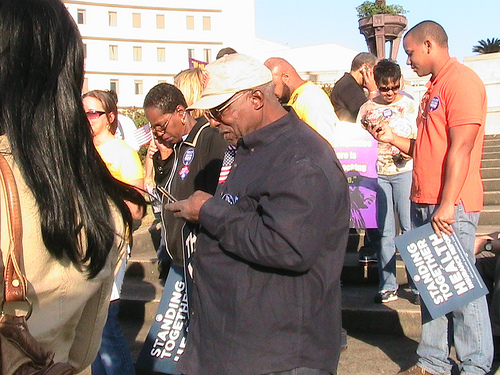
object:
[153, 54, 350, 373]
old man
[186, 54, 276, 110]
white hat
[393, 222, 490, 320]
blue sign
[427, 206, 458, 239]
hand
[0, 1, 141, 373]
long haired woman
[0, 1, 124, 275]
black hair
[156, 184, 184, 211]
phone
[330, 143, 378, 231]
poster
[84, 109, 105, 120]
sunglasses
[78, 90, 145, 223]
woman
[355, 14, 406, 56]
statue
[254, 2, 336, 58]
sky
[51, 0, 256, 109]
building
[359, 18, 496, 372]
man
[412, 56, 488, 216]
shirt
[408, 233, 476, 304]
white writing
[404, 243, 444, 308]
standing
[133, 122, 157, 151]
american flag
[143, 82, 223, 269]
lady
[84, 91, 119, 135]
brown hair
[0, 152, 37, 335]
brown strap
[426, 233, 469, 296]
health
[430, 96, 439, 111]
button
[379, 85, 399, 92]
dark sunglasses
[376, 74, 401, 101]
face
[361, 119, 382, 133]
cell phone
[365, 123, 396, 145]
hand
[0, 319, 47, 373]
purse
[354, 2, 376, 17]
plant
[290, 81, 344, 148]
yellow shirt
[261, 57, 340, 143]
bald man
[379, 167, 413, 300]
jeans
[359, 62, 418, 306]
female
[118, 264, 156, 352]
shadow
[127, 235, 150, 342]
floor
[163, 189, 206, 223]
hand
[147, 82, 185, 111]
hair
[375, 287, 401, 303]
shoe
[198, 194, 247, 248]
sleeve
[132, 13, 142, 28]
window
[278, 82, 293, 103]
beard